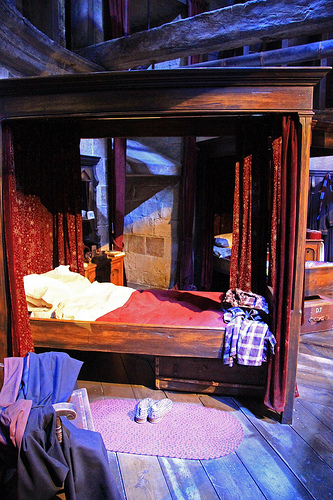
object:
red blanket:
[92, 284, 229, 326]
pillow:
[16, 264, 97, 309]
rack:
[298, 258, 331, 334]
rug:
[94, 398, 242, 460]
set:
[1, 2, 332, 499]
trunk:
[155, 357, 264, 396]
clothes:
[3, 357, 122, 498]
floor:
[1, 320, 332, 498]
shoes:
[134, 396, 153, 426]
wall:
[124, 176, 176, 287]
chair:
[0, 349, 98, 497]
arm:
[51, 401, 76, 421]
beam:
[73, 2, 332, 69]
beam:
[1, 0, 106, 73]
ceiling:
[7, 0, 332, 83]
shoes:
[147, 397, 175, 427]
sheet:
[37, 273, 234, 323]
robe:
[221, 286, 264, 364]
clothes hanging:
[317, 175, 332, 250]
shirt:
[218, 311, 274, 372]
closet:
[306, 160, 330, 284]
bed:
[0, 69, 315, 427]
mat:
[79, 394, 246, 462]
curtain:
[266, 116, 299, 417]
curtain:
[227, 119, 267, 291]